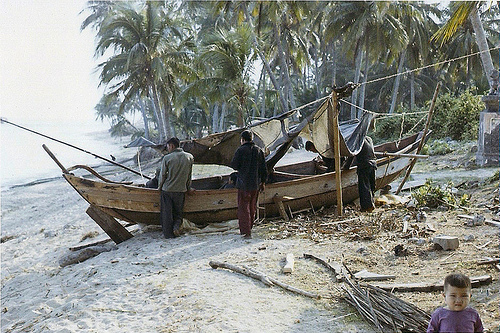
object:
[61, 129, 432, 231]
boat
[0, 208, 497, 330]
land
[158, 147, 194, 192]
shirt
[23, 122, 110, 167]
water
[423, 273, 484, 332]
boy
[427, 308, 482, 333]
shirt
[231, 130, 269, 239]
man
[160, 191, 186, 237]
black pants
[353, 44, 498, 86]
rope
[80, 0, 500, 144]
palm trees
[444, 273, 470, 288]
short hair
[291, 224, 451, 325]
ground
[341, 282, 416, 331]
sticks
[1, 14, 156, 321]
beach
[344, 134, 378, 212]
man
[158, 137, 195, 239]
man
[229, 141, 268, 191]
jacket